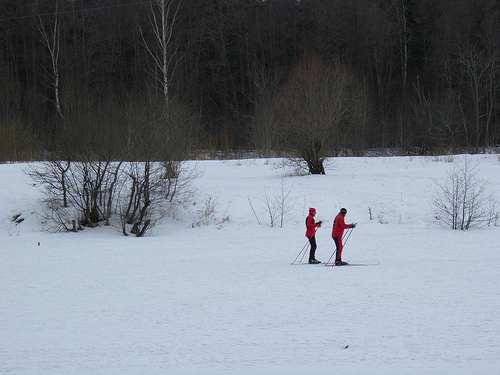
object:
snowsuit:
[331, 213, 352, 262]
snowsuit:
[305, 214, 318, 260]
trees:
[439, 152, 481, 227]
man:
[332, 207, 357, 265]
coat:
[305, 214, 317, 236]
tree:
[52, 2, 65, 119]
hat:
[340, 208, 348, 213]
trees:
[24, 141, 72, 207]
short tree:
[404, 74, 460, 161]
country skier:
[305, 207, 323, 265]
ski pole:
[292, 225, 319, 264]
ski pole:
[299, 242, 310, 262]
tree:
[151, 0, 176, 179]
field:
[0, 227, 499, 374]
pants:
[332, 236, 344, 261]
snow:
[0, 155, 499, 375]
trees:
[271, 53, 363, 175]